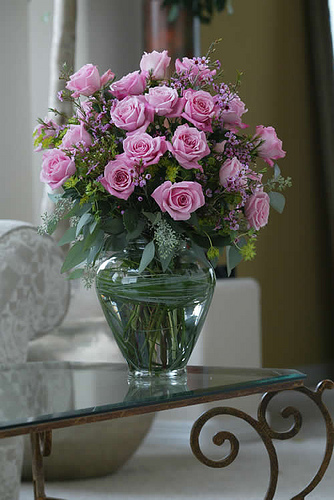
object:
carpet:
[20, 388, 333, 498]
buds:
[31, 38, 293, 292]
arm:
[0, 217, 70, 365]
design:
[0, 221, 72, 341]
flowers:
[32, 50, 287, 232]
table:
[0, 359, 307, 433]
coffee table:
[12, 330, 317, 431]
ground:
[249, 57, 282, 92]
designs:
[189, 378, 333, 500]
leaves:
[209, 195, 229, 215]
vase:
[95, 241, 216, 387]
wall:
[0, 0, 332, 393]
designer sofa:
[1, 214, 77, 498]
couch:
[0, 217, 74, 498]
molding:
[142, 0, 199, 63]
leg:
[29, 428, 52, 498]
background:
[1, 2, 334, 500]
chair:
[0, 209, 75, 498]